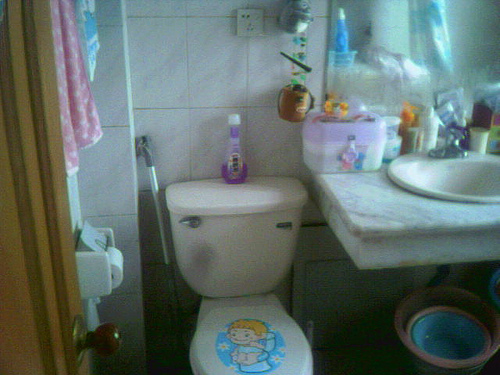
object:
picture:
[212, 316, 289, 375]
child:
[226, 318, 276, 373]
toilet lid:
[188, 299, 317, 375]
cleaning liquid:
[219, 110, 250, 187]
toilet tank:
[162, 172, 311, 299]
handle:
[66, 315, 125, 364]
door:
[0, 1, 100, 374]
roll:
[102, 242, 128, 293]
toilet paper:
[103, 244, 128, 294]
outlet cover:
[236, 7, 266, 38]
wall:
[120, 0, 499, 375]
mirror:
[324, 2, 496, 131]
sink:
[384, 145, 499, 211]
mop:
[140, 130, 191, 374]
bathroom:
[4, 0, 500, 373]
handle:
[175, 217, 203, 231]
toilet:
[160, 174, 320, 374]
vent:
[290, 220, 413, 354]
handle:
[445, 127, 467, 141]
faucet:
[424, 124, 472, 161]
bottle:
[219, 109, 251, 185]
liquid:
[223, 161, 248, 186]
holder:
[74, 224, 118, 305]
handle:
[137, 135, 156, 170]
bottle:
[416, 105, 441, 157]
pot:
[391, 282, 500, 374]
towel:
[47, 1, 108, 177]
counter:
[304, 149, 499, 271]